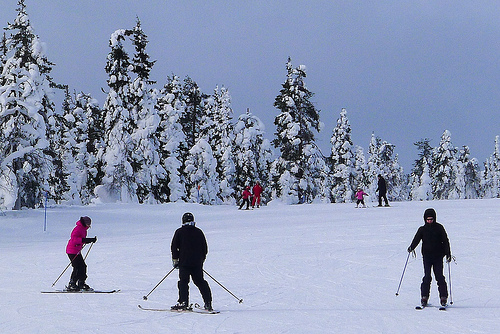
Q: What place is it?
A: It is a plain.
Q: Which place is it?
A: It is a plain.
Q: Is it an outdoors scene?
A: Yes, it is outdoors.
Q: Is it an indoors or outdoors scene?
A: It is outdoors.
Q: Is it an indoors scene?
A: No, it is outdoors.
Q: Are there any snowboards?
A: No, there are no snowboards.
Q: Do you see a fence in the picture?
A: No, there are no fences.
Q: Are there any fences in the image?
A: No, there are no fences.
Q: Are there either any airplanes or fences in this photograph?
A: No, there are no fences or airplanes.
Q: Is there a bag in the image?
A: No, there are no bags.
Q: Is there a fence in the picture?
A: No, there are no fences.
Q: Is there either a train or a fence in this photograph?
A: No, there are no fences or trains.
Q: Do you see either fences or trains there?
A: No, there are no fences or trains.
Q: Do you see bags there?
A: No, there are no bags.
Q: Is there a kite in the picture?
A: No, there are no kites.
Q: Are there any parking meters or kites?
A: No, there are no kites or parking meters.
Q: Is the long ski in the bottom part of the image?
A: Yes, the ski is in the bottom of the image.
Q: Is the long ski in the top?
A: No, the ski is in the bottom of the image.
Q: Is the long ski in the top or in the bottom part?
A: The ski is in the bottom of the image.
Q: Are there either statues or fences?
A: No, there are no fences or statues.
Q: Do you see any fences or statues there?
A: No, there are no fences or statues.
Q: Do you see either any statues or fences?
A: No, there are no fences or statues.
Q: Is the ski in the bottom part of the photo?
A: Yes, the ski is in the bottom of the image.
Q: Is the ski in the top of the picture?
A: No, the ski is in the bottom of the image.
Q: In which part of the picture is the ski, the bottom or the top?
A: The ski is in the bottom of the image.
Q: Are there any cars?
A: No, there are no cars.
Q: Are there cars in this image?
A: No, there are no cars.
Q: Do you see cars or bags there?
A: No, there are no cars or bags.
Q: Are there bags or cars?
A: No, there are no cars or bags.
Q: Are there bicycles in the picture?
A: No, there are no bicycles.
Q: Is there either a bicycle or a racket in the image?
A: No, there are no bicycles or rackets.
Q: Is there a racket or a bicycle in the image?
A: No, there are no bicycles or rackets.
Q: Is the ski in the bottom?
A: Yes, the ski is in the bottom of the image.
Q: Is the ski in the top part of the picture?
A: No, the ski is in the bottom of the image.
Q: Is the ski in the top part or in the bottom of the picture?
A: The ski is in the bottom of the image.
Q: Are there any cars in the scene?
A: No, there are no cars.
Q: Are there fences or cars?
A: No, there are no cars or fences.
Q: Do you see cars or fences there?
A: No, there are no cars or fences.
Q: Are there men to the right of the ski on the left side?
A: Yes, there is a man to the right of the ski.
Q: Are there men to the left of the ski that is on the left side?
A: No, the man is to the right of the ski.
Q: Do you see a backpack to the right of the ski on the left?
A: No, there is a man to the right of the ski.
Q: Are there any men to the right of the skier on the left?
A: Yes, there is a man to the right of the skier.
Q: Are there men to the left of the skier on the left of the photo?
A: No, the man is to the right of the skier.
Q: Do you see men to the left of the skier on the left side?
A: No, the man is to the right of the skier.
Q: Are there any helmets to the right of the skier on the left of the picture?
A: No, there is a man to the right of the skier.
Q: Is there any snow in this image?
A: Yes, there is snow.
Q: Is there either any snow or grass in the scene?
A: Yes, there is snow.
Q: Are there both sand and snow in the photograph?
A: No, there is snow but no sand.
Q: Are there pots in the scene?
A: No, there are no pots.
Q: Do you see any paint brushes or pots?
A: No, there are no pots or paint brushes.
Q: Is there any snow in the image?
A: Yes, there is snow.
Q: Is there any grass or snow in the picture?
A: Yes, there is snow.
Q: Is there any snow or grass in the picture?
A: Yes, there is snow.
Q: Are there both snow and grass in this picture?
A: No, there is snow but no grass.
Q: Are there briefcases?
A: No, there are no briefcases.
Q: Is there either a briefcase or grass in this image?
A: No, there are no briefcases or grass.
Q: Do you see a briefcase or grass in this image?
A: No, there are no briefcases or grass.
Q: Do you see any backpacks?
A: No, there are no backpacks.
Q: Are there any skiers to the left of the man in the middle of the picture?
A: Yes, there is a skier to the left of the man.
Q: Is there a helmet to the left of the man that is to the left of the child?
A: No, there is a skier to the left of the man.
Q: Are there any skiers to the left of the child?
A: Yes, there is a skier to the left of the child.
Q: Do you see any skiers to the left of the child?
A: Yes, there is a skier to the left of the child.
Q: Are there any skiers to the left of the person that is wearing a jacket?
A: Yes, there is a skier to the left of the child.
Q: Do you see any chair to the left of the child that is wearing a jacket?
A: No, there is a skier to the left of the kid.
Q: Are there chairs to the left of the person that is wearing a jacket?
A: No, there is a skier to the left of the kid.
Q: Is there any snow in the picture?
A: Yes, there is snow.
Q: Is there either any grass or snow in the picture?
A: Yes, there is snow.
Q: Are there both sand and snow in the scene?
A: No, there is snow but no sand.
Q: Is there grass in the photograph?
A: No, there is no grass.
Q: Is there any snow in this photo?
A: Yes, there is snow.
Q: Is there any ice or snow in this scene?
A: Yes, there is snow.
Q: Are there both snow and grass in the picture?
A: No, there is snow but no grass.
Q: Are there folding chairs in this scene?
A: No, there are no folding chairs.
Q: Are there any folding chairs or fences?
A: No, there are no folding chairs or fences.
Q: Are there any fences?
A: No, there are no fences.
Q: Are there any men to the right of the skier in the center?
A: Yes, there is a man to the right of the skier.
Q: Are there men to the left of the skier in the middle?
A: No, the man is to the right of the skier.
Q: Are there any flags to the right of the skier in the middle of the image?
A: No, there is a man to the right of the skier.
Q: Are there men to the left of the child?
A: Yes, there is a man to the left of the child.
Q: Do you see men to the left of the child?
A: Yes, there is a man to the left of the child.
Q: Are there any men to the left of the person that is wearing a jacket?
A: Yes, there is a man to the left of the child.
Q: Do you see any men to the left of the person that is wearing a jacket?
A: Yes, there is a man to the left of the child.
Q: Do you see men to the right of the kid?
A: No, the man is to the left of the kid.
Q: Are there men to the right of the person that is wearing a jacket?
A: No, the man is to the left of the kid.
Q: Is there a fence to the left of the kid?
A: No, there is a man to the left of the kid.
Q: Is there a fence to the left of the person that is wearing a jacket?
A: No, there is a man to the left of the kid.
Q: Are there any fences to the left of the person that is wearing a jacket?
A: No, there is a man to the left of the kid.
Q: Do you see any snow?
A: Yes, there is snow.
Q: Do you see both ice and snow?
A: No, there is snow but no ice.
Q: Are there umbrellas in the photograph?
A: No, there are no umbrellas.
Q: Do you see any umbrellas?
A: No, there are no umbrellas.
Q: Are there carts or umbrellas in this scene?
A: No, there are no umbrellas or carts.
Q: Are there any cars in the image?
A: No, there are no cars.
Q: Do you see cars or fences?
A: No, there are no cars or fences.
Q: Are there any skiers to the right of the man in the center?
A: Yes, there is a skier to the right of the man.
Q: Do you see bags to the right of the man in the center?
A: No, there is a skier to the right of the man.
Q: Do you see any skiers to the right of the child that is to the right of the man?
A: Yes, there is a skier to the right of the child.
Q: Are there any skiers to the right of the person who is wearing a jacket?
A: Yes, there is a skier to the right of the child.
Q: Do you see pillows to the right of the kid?
A: No, there is a skier to the right of the kid.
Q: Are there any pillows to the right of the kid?
A: No, there is a skier to the right of the kid.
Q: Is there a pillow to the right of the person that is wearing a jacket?
A: No, there is a skier to the right of the kid.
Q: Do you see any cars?
A: No, there are no cars.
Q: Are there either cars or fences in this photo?
A: No, there are no cars or fences.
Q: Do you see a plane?
A: No, there are no airplanes.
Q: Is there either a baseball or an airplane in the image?
A: No, there are no airplanes or baseballs.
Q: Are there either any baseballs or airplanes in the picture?
A: No, there are no airplanes or baseballs.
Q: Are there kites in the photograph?
A: No, there are no kites.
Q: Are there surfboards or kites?
A: No, there are no kites or surfboards.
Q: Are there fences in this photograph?
A: No, there are no fences.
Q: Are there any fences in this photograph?
A: No, there are no fences.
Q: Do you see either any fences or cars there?
A: No, there are no fences or cars.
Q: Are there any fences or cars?
A: No, there are no cars or fences.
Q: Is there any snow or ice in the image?
A: Yes, there is snow.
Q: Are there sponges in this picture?
A: No, there are no sponges.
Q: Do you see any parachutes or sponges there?
A: No, there are no sponges or parachutes.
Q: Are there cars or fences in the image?
A: No, there are no fences or cars.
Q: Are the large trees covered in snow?
A: Yes, the trees are covered in snow.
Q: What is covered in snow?
A: The trees are covered in snow.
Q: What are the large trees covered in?
A: The trees are covered in snow.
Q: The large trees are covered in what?
A: The trees are covered in snow.